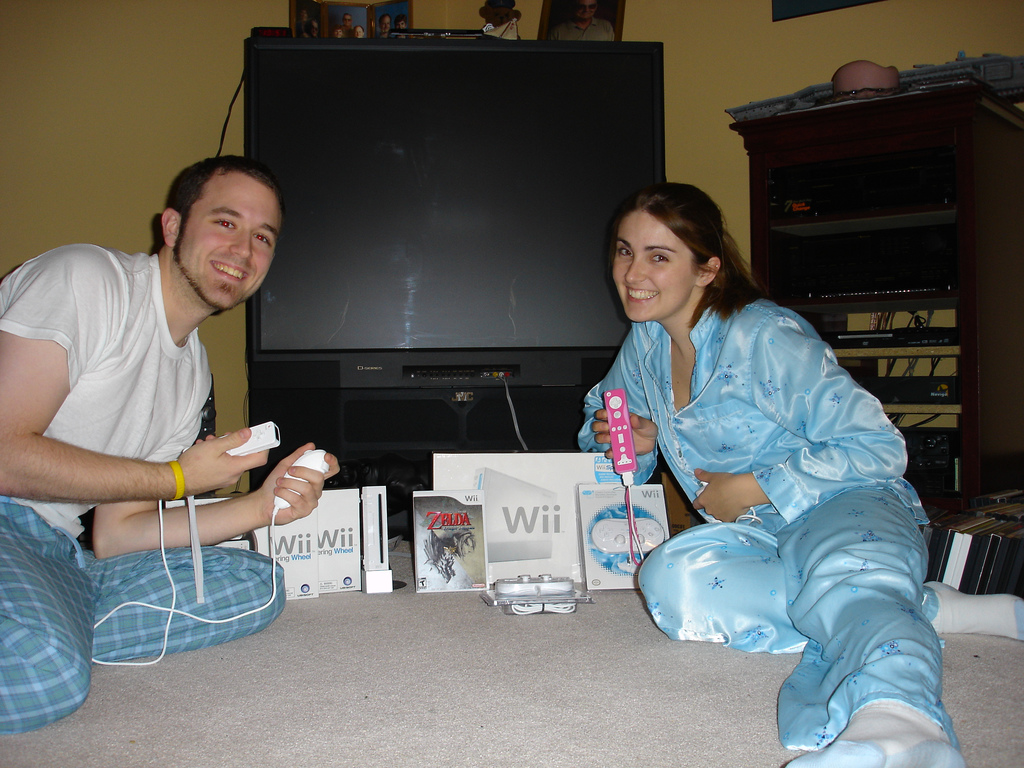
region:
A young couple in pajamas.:
[21, 166, 1023, 764]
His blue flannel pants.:
[12, 527, 295, 747]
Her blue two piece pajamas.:
[541, 286, 1017, 765]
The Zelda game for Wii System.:
[397, 443, 587, 589]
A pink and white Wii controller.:
[575, 378, 659, 537]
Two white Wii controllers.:
[187, 419, 344, 543]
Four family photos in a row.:
[280, 7, 639, 43]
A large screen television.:
[284, 48, 616, 390]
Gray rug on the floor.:
[325, 621, 658, 767]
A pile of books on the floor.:
[936, 478, 1020, 602]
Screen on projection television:
[240, 39, 678, 356]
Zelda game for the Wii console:
[404, 490, 488, 595]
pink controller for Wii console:
[596, 378, 677, 547]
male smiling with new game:
[5, 149, 331, 712]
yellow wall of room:
[10, 10, 216, 138]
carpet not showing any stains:
[313, 629, 636, 751]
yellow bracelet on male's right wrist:
[154, 435, 224, 513]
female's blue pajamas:
[625, 334, 955, 693]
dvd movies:
[916, 492, 1021, 579]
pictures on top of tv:
[280, 1, 439, 36]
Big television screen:
[292, 27, 605, 363]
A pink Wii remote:
[577, 381, 650, 547]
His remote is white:
[197, 418, 360, 565]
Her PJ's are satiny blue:
[598, 182, 893, 752]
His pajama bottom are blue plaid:
[11, 156, 255, 766]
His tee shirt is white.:
[16, 244, 220, 491]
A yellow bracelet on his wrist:
[149, 444, 203, 512]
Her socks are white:
[762, 570, 1007, 764]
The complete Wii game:
[361, 438, 627, 642]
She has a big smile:
[583, 212, 748, 326]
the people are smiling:
[100, 144, 714, 375]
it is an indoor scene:
[26, 220, 880, 718]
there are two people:
[49, 213, 938, 748]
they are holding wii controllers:
[17, 226, 776, 539]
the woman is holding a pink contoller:
[552, 336, 723, 568]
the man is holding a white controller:
[153, 261, 395, 588]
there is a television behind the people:
[249, 260, 630, 385]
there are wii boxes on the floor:
[242, 437, 696, 685]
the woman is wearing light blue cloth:
[563, 252, 919, 737]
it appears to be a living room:
[132, 88, 900, 765]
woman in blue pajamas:
[572, 180, 974, 766]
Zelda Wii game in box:
[410, 490, 493, 592]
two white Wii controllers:
[205, 418, 329, 513]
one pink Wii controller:
[604, 386, 639, 476]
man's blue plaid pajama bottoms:
[2, 496, 287, 734]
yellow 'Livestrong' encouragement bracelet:
[168, 458, 188, 503]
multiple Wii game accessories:
[161, 450, 674, 613]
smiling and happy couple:
[5, 156, 1023, 766]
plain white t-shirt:
[2, 246, 214, 532]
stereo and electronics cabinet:
[729, 77, 1023, 511]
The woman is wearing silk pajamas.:
[584, 181, 1002, 766]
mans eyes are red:
[212, 196, 277, 263]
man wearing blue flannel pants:
[4, 497, 283, 703]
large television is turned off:
[250, 32, 665, 350]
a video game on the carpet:
[405, 487, 481, 592]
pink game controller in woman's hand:
[598, 386, 640, 557]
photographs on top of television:
[276, 0, 410, 43]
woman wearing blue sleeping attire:
[577, 317, 945, 750]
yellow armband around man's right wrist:
[164, 457, 188, 505]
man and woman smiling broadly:
[155, 159, 719, 316]